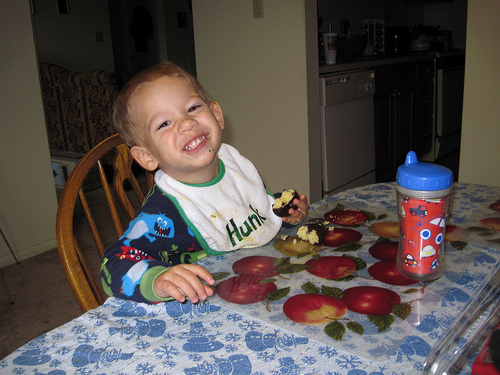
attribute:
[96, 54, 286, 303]
kid — small, white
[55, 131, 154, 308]
chair — large, brown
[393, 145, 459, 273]
cup — tall, large, red and blue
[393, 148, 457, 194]
cup lid — large, round, blue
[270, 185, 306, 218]
food — white, crushed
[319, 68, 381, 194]
machine — large, white, square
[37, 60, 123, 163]
couch — large, floral, cloth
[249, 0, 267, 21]
light switch — small, square, white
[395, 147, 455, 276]
sippy cup — red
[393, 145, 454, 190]
lid — blue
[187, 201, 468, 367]
place mat — clear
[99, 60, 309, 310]
boy — small, smiling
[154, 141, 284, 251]
bib — large, thin, white, white, lined in green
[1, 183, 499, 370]
tablecloth — blue and white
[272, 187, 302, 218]
bowl — small, black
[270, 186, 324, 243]
egg — scrambled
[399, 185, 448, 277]
cup — clear, plastic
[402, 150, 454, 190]
sippie lid — blue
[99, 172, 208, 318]
pajamas — monster, blue, green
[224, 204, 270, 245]
hunk — green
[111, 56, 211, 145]
hair — short, curly, blonde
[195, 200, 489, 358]
place mat — clear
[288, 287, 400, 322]
apple — red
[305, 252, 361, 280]
apple — red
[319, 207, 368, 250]
apple — red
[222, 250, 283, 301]
apple — red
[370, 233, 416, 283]
apple — red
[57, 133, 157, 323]
chair — brown, wooden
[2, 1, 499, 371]
kitchen scene — indoor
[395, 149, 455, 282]
cup — sippy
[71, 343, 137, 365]
snowman — blue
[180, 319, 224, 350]
snowman — blue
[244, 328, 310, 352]
snowman — blue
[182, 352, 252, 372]
snowman — blue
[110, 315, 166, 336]
snowman — blue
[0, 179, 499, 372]
table cloth — large, blue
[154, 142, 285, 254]
baby bib — green, white